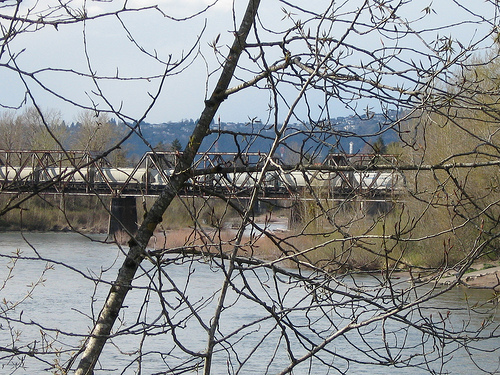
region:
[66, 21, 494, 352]
branches of a tree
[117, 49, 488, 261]
bunch of tree branches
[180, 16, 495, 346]
bunch of tree branches on a tree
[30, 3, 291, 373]
a tree with bunch of branches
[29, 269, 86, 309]
a body of water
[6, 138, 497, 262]
a bridge over a body of water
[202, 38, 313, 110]
tree branch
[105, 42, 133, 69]
a clear sky with now clouds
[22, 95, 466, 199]
trees and branches in the background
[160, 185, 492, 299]
bushes near a body of water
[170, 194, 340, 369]
the branches are barren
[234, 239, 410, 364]
the branches are barren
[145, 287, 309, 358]
the branches are barren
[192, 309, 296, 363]
the branches are barren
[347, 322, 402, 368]
the water is calm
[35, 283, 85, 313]
the water is calm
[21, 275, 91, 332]
the water is calm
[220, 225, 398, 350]
a barren tree branch without leaves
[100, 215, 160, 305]
the skinny trunk of a tree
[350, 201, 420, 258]
dead grass growing by a lake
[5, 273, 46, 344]
small leaves sprouting on a plant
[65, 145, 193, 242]
a small bridge made for trains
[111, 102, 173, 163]
a bunch of green trees in the distance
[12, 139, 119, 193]
the safety gate of a bridge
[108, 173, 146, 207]
small brown steel train tracks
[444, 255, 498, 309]
the brown coast of a lake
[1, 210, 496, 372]
Water in the forefront.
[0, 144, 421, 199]
Bridge over the water.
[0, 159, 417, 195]
Train on the tracks.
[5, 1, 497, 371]
Tree branches in the forefront.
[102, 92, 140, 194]
Support wall on the bridge.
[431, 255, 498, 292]
Dirt on the bank.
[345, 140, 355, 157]
Pole in the background.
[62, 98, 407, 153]
Trees in the background.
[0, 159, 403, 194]
White color on the trains.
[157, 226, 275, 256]
Brown grass on the bank.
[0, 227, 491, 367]
calm light-blue water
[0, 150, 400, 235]
train crossing over bridge on upright support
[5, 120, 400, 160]
slope of trees in back of train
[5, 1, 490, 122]
light-blue sky with a few clouds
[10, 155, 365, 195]
bridge beams in triangular formations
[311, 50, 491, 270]
tree with fuzzy light-green growth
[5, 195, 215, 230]
marsh under bridge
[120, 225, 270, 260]
tan plants on land extending into water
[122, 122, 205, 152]
houses on hills in distance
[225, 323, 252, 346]
A dead looking stem.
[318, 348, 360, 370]
A dead looking stem.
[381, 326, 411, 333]
A dead looking stem.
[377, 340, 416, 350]
A dead looking stem.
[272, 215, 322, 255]
A dead looking stem.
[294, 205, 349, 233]
A dead looking stem.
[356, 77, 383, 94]
A dead looking stem.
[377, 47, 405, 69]
A dead looking stem.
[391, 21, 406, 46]
A dead looking stem.